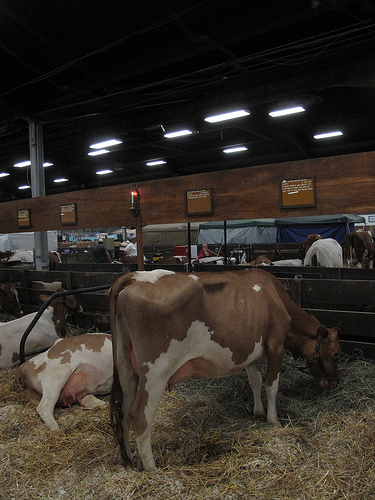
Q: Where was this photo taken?
A: In a barn.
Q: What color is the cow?
A: Brown and white.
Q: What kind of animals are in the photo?
A: Cows.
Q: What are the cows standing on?
A: Straw.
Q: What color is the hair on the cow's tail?
A: Black.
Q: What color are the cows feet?
A: White.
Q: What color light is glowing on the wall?
A: Red.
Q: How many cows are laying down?
A: Two.